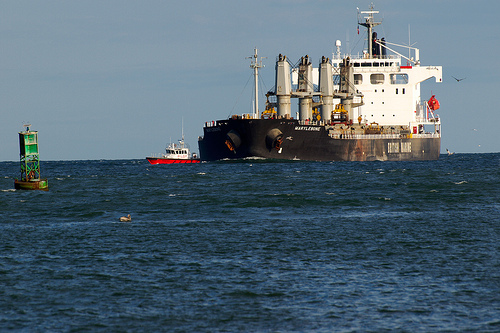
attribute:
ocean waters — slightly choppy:
[92, 156, 249, 271]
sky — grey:
[68, 42, 133, 117]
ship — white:
[277, 54, 457, 139]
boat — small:
[145, 139, 201, 166]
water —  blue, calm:
[0, 152, 496, 329]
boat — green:
[10, 122, 50, 190]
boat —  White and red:
[139, 136, 217, 171]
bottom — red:
[140, 149, 206, 163]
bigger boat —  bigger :
[191, 3, 454, 167]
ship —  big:
[168, 27, 425, 164]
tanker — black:
[203, 111, 430, 162]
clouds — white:
[35, 30, 160, 92]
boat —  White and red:
[142, 133, 202, 168]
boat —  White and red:
[139, 115, 219, 201]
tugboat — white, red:
[141, 129, 201, 161]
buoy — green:
[14, 124, 49, 191]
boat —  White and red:
[131, 140, 206, 176]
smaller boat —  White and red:
[147, 114, 204, 169]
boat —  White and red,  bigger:
[156, 139, 211, 174]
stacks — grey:
[336, 55, 360, 126]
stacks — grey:
[316, 52, 336, 126]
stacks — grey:
[291, 52, 318, 124]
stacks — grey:
[273, 50, 294, 120]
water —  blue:
[83, 217, 233, 303]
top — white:
[161, 143, 188, 157]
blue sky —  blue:
[58, 42, 214, 113]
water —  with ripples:
[206, 238, 384, 302]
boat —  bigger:
[196, 35, 439, 163]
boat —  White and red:
[148, 115, 198, 166]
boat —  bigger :
[198, 7, 448, 156]